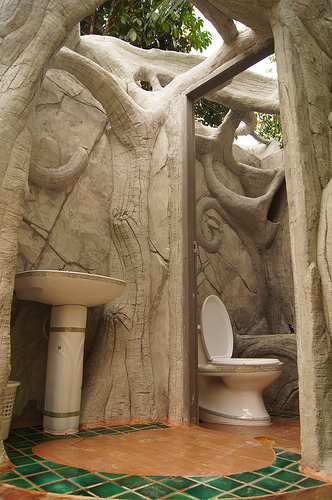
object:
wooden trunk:
[0, 0, 332, 470]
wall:
[0, 0, 195, 436]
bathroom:
[0, 0, 332, 500]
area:
[0, 416, 332, 500]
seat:
[198, 357, 286, 377]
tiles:
[83, 480, 128, 500]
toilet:
[197, 295, 284, 427]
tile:
[181, 479, 222, 499]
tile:
[112, 425, 137, 434]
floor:
[0, 411, 332, 500]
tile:
[92, 427, 122, 437]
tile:
[53, 433, 78, 438]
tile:
[25, 431, 54, 445]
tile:
[8, 438, 33, 456]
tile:
[13, 460, 51, 476]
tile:
[24, 471, 65, 486]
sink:
[15, 268, 127, 307]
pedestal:
[42, 304, 87, 437]